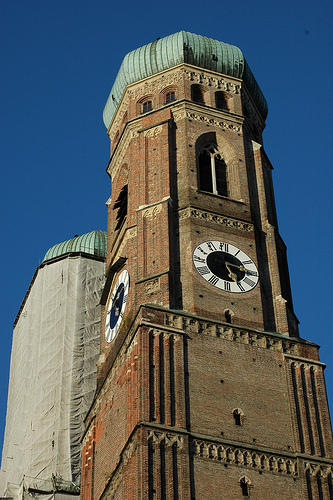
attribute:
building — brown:
[0, 230, 97, 497]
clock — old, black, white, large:
[188, 236, 274, 310]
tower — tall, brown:
[89, 32, 329, 499]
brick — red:
[151, 150, 172, 178]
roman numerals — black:
[191, 247, 221, 288]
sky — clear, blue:
[1, 4, 333, 338]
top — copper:
[44, 223, 106, 259]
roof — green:
[99, 34, 261, 121]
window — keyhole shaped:
[228, 402, 256, 430]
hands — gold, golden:
[224, 261, 256, 287]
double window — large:
[197, 144, 244, 205]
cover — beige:
[51, 260, 99, 402]